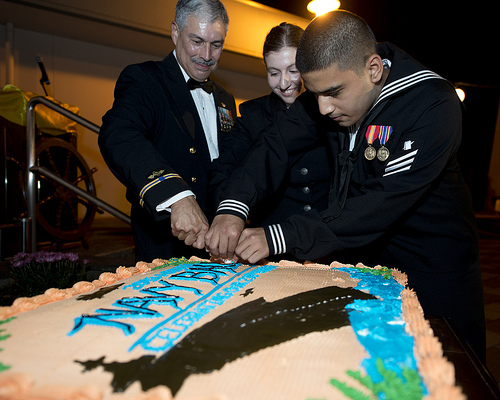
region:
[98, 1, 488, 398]
two men and a woman in uniforms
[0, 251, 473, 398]
large decorated cake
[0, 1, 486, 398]
people cutting cake together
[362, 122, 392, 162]
awards on uniform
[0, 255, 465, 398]
blue, green, white, and black icing on cake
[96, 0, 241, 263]
man is wearing a bow tie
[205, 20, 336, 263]
woman is smiling at cake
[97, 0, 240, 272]
man has gray hair and mustache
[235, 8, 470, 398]
man leaning over cake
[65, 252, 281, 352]
writing in icing on cake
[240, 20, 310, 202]
woman looking at cake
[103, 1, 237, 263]
officer cutting cake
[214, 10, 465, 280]
people cutting a cake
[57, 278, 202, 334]
the word NAVY written in blue and brown icing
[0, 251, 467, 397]
a very large sheet cake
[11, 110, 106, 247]
a ships wheel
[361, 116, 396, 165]
medals pinned to a military jacket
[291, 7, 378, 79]
a short military hair cut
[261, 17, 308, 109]
a woman's smiling face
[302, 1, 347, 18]
a bright overhead light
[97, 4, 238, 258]
A older man in uniform.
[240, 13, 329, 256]
A young lady wearing a uniform.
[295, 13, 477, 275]
A young man in uniform.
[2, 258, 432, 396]
A cake with white frosting.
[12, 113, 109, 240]
A wheel to steer a boat.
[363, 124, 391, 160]
Medals he gained in the navy.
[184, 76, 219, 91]
Black bow tie.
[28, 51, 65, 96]
A microphone for speaking.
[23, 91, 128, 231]
A rail to hold on to.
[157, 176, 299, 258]
Cutting into the cake together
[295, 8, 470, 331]
a sailor with medals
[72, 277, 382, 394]
submarine on a cake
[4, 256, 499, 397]
a cake decorated with icing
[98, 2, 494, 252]
three Navy personnel cutting cake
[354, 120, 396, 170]
two Navy medals on a uniform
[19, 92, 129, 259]
a handrail in the background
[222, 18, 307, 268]
a female Navy person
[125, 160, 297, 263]
Navy rank on sleeve cuffs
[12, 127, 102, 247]
a nautical steering wheel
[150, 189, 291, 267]
three hands at cake cutting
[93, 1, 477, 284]
Three people cutting into a cake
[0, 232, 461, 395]
Cake decorated with the word Navy and a submarine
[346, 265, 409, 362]
Blue icing on a cake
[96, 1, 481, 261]
Two men and one woman in Navy uniforms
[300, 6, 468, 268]
A man in a navy uniform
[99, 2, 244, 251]
A man with many medals on his Navy uniform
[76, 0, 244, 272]
A man with gray hair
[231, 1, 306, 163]
A woman with brown hair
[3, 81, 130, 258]
A railing for stairs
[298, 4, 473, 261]
A man with brown hair